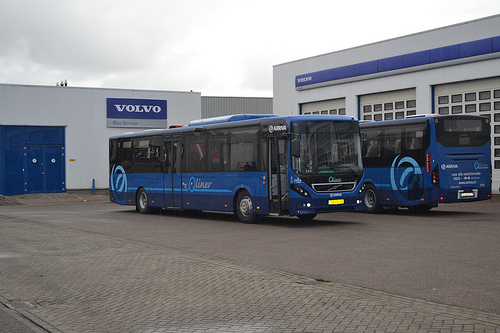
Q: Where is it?
A: This is at the road.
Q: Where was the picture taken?
A: It was taken at the road.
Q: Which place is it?
A: It is a road.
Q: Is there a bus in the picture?
A: Yes, there is a bus.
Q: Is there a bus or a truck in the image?
A: Yes, there is a bus.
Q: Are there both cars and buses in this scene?
A: No, there is a bus but no cars.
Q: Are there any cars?
A: No, there are no cars.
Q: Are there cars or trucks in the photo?
A: No, there are no cars or trucks.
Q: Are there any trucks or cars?
A: No, there are no cars or trucks.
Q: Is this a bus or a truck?
A: This is a bus.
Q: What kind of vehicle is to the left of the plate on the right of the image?
A: The vehicle is a bus.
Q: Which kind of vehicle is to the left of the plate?
A: The vehicle is a bus.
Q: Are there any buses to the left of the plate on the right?
A: Yes, there is a bus to the left of the plate.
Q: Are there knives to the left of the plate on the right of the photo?
A: No, there is a bus to the left of the plate.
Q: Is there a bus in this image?
A: Yes, there is a bus.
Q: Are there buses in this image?
A: Yes, there is a bus.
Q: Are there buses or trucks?
A: Yes, there is a bus.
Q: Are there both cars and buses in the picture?
A: No, there is a bus but no cars.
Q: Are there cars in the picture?
A: No, there are no cars.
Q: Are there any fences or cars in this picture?
A: No, there are no cars or fences.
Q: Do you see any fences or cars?
A: No, there are no cars or fences.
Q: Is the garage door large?
A: Yes, the garage door is large.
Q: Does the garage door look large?
A: Yes, the garage door is large.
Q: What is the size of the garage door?
A: The garage door is large.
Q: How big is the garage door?
A: The garage door is large.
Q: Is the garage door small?
A: No, the garage door is large.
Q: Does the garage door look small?
A: No, the garage door is large.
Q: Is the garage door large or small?
A: The garage door is large.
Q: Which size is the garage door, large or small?
A: The garage door is large.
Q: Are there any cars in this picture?
A: No, there are no cars.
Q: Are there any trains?
A: No, there are no trains.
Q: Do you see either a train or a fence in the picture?
A: No, there are no trains or fences.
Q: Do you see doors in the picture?
A: Yes, there is a door.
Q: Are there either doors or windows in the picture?
A: Yes, there is a door.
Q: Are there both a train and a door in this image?
A: No, there is a door but no trains.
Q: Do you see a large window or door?
A: Yes, there is a large door.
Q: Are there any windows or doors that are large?
A: Yes, the door is large.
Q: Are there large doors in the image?
A: Yes, there is a large door.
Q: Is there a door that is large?
A: Yes, there is a door that is large.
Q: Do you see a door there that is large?
A: Yes, there is a door that is large.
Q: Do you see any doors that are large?
A: Yes, there is a door that is large.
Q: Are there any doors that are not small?
A: Yes, there is a large door.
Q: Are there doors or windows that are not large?
A: No, there is a door but it is large.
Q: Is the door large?
A: Yes, the door is large.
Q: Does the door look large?
A: Yes, the door is large.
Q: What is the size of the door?
A: The door is large.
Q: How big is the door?
A: The door is large.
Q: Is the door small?
A: No, the door is large.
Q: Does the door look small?
A: No, the door is large.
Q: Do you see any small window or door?
A: No, there is a door but it is large.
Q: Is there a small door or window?
A: No, there is a door but it is large.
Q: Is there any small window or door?
A: No, there is a door but it is large.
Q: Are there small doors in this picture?
A: No, there is a door but it is large.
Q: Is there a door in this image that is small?
A: No, there is a door but it is large.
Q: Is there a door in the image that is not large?
A: No, there is a door but it is large.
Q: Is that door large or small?
A: The door is large.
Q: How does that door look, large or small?
A: The door is large.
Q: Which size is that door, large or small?
A: The door is large.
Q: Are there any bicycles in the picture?
A: No, there are no bicycles.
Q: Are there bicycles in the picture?
A: No, there are no bicycles.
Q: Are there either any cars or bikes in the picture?
A: No, there are no bikes or cars.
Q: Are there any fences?
A: No, there are no fences.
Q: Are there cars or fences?
A: No, there are no fences or cars.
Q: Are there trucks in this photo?
A: No, there are no trucks.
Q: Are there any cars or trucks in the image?
A: No, there are no trucks or cars.